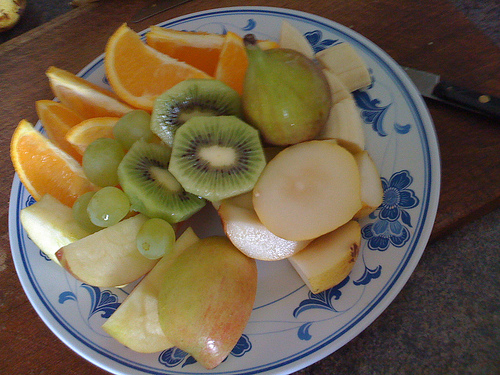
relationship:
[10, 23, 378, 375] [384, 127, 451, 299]
fruit on plate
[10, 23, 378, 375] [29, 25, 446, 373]
fruit on plate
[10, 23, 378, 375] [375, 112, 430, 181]
fruit on plate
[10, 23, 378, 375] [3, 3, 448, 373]
fruit on plate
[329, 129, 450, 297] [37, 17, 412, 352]
design on white plate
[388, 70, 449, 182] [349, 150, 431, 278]
design on plate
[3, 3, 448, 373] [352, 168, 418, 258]
plate has design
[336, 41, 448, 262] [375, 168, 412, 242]
white plate has blue design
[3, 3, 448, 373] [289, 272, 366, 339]
plate has design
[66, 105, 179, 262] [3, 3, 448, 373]
grapes on plate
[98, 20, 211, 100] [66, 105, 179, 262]
orange besides grapes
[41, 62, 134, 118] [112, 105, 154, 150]
orange slice next to grape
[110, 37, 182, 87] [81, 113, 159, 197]
slice next to grape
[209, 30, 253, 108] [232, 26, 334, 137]
slice next to grape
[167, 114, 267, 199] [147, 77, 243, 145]
kiwi below kiwi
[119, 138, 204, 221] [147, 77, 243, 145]
kiwi below kiwi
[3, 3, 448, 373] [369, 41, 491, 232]
plate on table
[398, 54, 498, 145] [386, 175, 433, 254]
knife next to blue plate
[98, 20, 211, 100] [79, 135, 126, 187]
orange by grape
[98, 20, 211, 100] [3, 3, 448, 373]
orange on plate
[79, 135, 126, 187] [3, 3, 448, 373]
grape on plate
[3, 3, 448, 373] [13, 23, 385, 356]
plate of fruit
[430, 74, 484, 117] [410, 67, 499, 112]
handle of knife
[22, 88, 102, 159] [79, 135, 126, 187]
orange next to grape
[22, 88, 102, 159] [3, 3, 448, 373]
orange on plate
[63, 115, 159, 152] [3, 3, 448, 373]
orange slice on plate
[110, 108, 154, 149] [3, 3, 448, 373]
grape on plate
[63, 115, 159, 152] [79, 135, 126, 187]
orange slice next to grape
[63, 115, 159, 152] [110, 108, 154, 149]
orange slice next to grape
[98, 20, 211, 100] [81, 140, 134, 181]
orange next to grape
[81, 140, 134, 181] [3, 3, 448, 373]
grape on plate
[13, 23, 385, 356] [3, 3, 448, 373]
fruit on plate